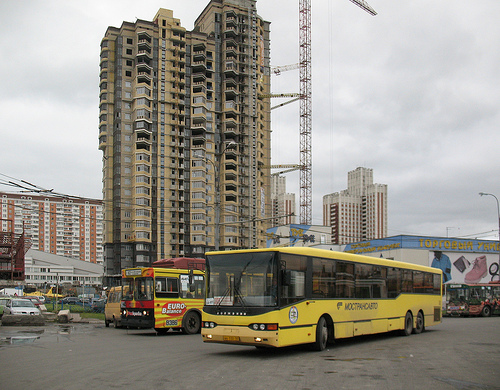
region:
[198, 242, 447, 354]
The bus is yellow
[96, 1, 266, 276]
The building is yellow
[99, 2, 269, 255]
The building is tall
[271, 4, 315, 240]
Crane next to the building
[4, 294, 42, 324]
The car is white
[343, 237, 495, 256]
Yellow writing on building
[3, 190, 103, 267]
White and orange building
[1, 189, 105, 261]
The building is striped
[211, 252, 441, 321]
Row of black windows on side of bus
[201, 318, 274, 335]
White and orange lights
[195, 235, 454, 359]
passenger bus is yellow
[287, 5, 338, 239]
ladder used to go up the building being built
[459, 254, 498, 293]
shoe on the side of building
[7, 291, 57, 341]
car in front of buses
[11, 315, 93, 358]
water in the road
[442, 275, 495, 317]
bus under the building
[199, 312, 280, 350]
lights on front of bus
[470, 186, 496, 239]
street light over the building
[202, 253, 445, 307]
windows on the bus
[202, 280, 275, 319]
windshield wipers on the bus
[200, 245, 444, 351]
a yellow public service bus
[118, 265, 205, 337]
a yellow and red public service bus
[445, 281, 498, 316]
a red public service bus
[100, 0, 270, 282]
large building in distance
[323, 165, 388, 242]
large building in distance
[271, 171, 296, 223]
large building in distance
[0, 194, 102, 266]
large building in distance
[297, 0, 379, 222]
a tall metal crane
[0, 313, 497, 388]
a paved roadway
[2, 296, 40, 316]
a parked white car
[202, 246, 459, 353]
large yellow bus with tinted windows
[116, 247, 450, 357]
two yellow buses parked next to each other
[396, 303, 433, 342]
two rear wheels on a bus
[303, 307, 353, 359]
front left bus wheel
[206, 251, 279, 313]
front windshield on a bus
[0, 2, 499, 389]
buses parked in front of an unfinished building in an urban area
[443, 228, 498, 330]
bus parked in front of a building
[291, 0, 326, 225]
support structure for a crane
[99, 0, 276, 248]
unfinished high rise building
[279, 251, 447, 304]
tinted side windows on a bus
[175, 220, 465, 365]
bus is light yellow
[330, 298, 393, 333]
bus has black writing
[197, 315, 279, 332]
bus has four headlights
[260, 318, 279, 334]
bus has orange light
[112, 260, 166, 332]
bus has red front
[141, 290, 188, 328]
bus has white writing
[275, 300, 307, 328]
bus has white decal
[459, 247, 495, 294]
brown shoe on building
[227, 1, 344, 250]
scaffolding attached to building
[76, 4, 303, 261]
building has multiple stories